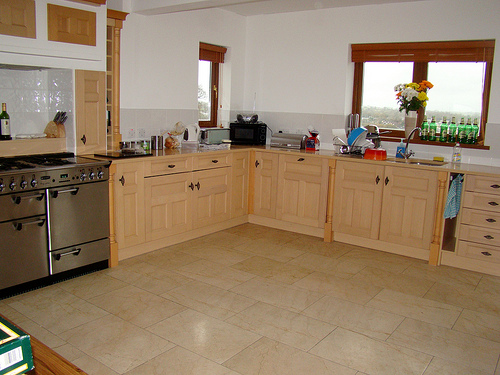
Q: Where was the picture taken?
A: It was taken at the kitchen.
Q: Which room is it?
A: It is a kitchen.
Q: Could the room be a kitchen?
A: Yes, it is a kitchen.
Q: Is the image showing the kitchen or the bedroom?
A: It is showing the kitchen.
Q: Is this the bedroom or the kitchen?
A: It is the kitchen.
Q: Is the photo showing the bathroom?
A: No, the picture is showing the kitchen.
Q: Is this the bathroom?
A: No, it is the kitchen.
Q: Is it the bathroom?
A: No, it is the kitchen.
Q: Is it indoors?
A: Yes, it is indoors.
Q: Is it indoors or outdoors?
A: It is indoors.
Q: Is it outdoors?
A: No, it is indoors.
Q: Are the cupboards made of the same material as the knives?
A: Yes, both the cupboards and the knives are made of wood.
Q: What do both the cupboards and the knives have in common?
A: The material, both the cupboards and the knives are wooden.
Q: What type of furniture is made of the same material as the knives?
A: The cupboards are made of the same material as the knives.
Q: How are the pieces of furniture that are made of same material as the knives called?
A: The pieces of furniture are cupboards.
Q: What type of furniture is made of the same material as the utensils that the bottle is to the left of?
A: The cupboards are made of the same material as the knives.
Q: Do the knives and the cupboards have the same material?
A: Yes, both the knives and the cupboards are made of wood.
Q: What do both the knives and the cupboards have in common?
A: The material, both the knives and the cupboards are wooden.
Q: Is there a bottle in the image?
A: Yes, there is a bottle.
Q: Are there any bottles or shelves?
A: Yes, there is a bottle.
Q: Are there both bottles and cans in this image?
A: No, there is a bottle but no cans.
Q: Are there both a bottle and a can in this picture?
A: No, there is a bottle but no cans.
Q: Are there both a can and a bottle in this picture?
A: No, there is a bottle but no cans.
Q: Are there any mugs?
A: No, there are no mugs.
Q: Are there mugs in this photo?
A: No, there are no mugs.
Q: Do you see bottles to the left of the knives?
A: Yes, there is a bottle to the left of the knives.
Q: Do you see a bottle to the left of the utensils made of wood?
A: Yes, there is a bottle to the left of the knives.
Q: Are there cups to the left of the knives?
A: No, there is a bottle to the left of the knives.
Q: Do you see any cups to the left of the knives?
A: No, there is a bottle to the left of the knives.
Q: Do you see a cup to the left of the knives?
A: No, there is a bottle to the left of the knives.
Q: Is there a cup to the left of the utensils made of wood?
A: No, there is a bottle to the left of the knives.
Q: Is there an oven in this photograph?
A: Yes, there is an oven.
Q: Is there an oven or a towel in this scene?
A: Yes, there is an oven.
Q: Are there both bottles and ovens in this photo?
A: Yes, there are both an oven and a bottle.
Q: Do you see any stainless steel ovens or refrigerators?
A: Yes, there is a stainless steel oven.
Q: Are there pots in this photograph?
A: No, there are no pots.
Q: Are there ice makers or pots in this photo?
A: No, there are no pots or ice makers.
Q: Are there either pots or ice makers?
A: No, there are no pots or ice makers.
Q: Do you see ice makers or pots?
A: No, there are no pots or ice makers.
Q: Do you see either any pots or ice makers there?
A: No, there are no pots or ice makers.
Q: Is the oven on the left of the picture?
A: Yes, the oven is on the left of the image.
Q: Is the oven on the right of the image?
A: No, the oven is on the left of the image.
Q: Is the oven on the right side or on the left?
A: The oven is on the left of the image.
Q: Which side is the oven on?
A: The oven is on the left of the image.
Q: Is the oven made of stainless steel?
A: Yes, the oven is made of stainless steel.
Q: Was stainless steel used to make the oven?
A: Yes, the oven is made of stainless steel.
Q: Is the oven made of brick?
A: No, the oven is made of stainless steel.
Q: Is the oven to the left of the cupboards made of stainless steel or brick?
A: The oven is made of stainless steel.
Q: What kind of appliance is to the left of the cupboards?
A: The appliance is an oven.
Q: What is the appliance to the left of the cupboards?
A: The appliance is an oven.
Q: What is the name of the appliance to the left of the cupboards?
A: The appliance is an oven.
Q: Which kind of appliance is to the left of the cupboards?
A: The appliance is an oven.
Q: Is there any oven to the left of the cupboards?
A: Yes, there is an oven to the left of the cupboards.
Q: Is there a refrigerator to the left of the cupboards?
A: No, there is an oven to the left of the cupboards.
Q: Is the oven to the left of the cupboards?
A: Yes, the oven is to the left of the cupboards.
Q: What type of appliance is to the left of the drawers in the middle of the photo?
A: The appliance is an oven.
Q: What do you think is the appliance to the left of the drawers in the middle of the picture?
A: The appliance is an oven.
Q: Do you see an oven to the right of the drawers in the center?
A: No, the oven is to the left of the drawers.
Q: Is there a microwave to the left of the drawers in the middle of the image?
A: No, there is an oven to the left of the drawers.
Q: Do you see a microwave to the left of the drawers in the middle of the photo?
A: No, there is an oven to the left of the drawers.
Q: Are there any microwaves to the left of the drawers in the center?
A: No, there is an oven to the left of the drawers.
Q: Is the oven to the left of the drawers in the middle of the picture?
A: Yes, the oven is to the left of the drawers.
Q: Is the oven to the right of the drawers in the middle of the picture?
A: No, the oven is to the left of the drawers.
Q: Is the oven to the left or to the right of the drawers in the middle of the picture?
A: The oven is to the left of the drawers.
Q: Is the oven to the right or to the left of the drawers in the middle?
A: The oven is to the left of the drawers.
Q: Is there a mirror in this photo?
A: No, there are no mirrors.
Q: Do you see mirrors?
A: No, there are no mirrors.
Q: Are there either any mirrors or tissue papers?
A: No, there are no mirrors or tissue papers.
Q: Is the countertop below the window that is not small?
A: Yes, the countertop is below the window.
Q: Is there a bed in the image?
A: No, there are no beds.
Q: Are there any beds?
A: No, there are no beds.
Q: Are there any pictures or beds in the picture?
A: No, there are no beds or pictures.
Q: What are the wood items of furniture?
A: The pieces of furniture are cupboards.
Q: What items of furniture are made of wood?
A: The pieces of furniture are cupboards.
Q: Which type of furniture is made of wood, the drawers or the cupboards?
A: The cupboards are made of wood.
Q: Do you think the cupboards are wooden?
A: Yes, the cupboards are wooden.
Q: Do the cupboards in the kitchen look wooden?
A: Yes, the cupboards are wooden.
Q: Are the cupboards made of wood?
A: Yes, the cupboards are made of wood.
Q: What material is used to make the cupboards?
A: The cupboards are made of wood.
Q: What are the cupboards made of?
A: The cupboards are made of wood.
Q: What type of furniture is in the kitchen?
A: The pieces of furniture are cupboards.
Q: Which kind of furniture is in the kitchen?
A: The pieces of furniture are cupboards.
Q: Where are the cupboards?
A: The cupboards are in the kitchen.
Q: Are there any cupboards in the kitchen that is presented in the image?
A: Yes, there are cupboards in the kitchen.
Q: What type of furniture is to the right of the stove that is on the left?
A: The pieces of furniture are cupboards.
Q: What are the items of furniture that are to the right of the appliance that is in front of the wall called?
A: The pieces of furniture are cupboards.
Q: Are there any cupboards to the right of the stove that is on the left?
A: Yes, there are cupboards to the right of the stove.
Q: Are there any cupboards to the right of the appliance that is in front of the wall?
A: Yes, there are cupboards to the right of the stove.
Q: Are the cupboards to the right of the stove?
A: Yes, the cupboards are to the right of the stove.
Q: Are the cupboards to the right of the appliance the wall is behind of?
A: Yes, the cupboards are to the right of the stove.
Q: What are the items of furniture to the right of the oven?
A: The pieces of furniture are cupboards.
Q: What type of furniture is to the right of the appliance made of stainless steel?
A: The pieces of furniture are cupboards.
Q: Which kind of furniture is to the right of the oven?
A: The pieces of furniture are cupboards.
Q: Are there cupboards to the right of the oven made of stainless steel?
A: Yes, there are cupboards to the right of the oven.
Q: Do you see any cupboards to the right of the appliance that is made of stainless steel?
A: Yes, there are cupboards to the right of the oven.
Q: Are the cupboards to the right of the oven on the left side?
A: Yes, the cupboards are to the right of the oven.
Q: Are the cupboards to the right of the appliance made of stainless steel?
A: Yes, the cupboards are to the right of the oven.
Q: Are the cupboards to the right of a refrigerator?
A: No, the cupboards are to the right of the oven.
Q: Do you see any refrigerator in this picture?
A: No, there are no refrigerators.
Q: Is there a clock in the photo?
A: No, there are no clocks.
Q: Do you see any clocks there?
A: No, there are no clocks.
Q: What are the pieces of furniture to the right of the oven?
A: The pieces of furniture are drawers.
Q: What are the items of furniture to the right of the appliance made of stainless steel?
A: The pieces of furniture are drawers.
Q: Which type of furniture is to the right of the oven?
A: The pieces of furniture are drawers.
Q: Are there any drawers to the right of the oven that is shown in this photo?
A: Yes, there are drawers to the right of the oven.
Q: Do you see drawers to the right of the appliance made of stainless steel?
A: Yes, there are drawers to the right of the oven.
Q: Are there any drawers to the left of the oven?
A: No, the drawers are to the right of the oven.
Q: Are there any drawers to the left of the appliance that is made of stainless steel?
A: No, the drawers are to the right of the oven.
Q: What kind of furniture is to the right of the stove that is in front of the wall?
A: The pieces of furniture are drawers.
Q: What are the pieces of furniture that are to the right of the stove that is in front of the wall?
A: The pieces of furniture are drawers.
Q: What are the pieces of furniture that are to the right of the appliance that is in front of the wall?
A: The pieces of furniture are drawers.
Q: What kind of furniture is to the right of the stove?
A: The pieces of furniture are drawers.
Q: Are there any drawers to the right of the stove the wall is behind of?
A: Yes, there are drawers to the right of the stove.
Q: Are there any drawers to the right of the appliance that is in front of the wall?
A: Yes, there are drawers to the right of the stove.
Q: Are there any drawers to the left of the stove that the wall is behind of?
A: No, the drawers are to the right of the stove.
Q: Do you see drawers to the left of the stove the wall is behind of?
A: No, the drawers are to the right of the stove.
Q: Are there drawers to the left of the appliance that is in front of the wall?
A: No, the drawers are to the right of the stove.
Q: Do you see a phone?
A: Yes, there is a phone.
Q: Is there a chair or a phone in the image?
A: Yes, there is a phone.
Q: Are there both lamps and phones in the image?
A: No, there is a phone but no lamps.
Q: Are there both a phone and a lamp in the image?
A: No, there is a phone but no lamps.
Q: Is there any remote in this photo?
A: No, there are no remote controls.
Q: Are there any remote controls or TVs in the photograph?
A: No, there are no remote controls or tvs.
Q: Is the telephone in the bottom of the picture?
A: Yes, the telephone is in the bottom of the image.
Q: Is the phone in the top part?
A: No, the phone is in the bottom of the image.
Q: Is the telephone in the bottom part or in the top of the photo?
A: The telephone is in the bottom of the image.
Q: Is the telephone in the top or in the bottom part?
A: The telephone is in the bottom of the image.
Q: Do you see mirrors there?
A: No, there are no mirrors.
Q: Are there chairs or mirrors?
A: No, there are no mirrors or chairs.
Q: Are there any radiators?
A: No, there are no radiators.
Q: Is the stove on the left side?
A: Yes, the stove is on the left of the image.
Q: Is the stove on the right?
A: No, the stove is on the left of the image.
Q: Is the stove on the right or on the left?
A: The stove is on the left of the image.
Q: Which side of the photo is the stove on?
A: The stove is on the left of the image.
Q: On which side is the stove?
A: The stove is on the left of the image.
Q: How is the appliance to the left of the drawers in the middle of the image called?
A: The appliance is a stove.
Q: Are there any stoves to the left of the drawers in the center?
A: Yes, there is a stove to the left of the drawers.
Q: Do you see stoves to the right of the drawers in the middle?
A: No, the stove is to the left of the drawers.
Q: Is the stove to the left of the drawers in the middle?
A: Yes, the stove is to the left of the drawers.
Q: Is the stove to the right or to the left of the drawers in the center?
A: The stove is to the left of the drawers.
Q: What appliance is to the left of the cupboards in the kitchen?
A: The appliance is a stove.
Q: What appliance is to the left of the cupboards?
A: The appliance is a stove.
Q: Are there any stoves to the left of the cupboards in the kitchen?
A: Yes, there is a stove to the left of the cupboards.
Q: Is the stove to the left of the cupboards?
A: Yes, the stove is to the left of the cupboards.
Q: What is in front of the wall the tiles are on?
A: The stove is in front of the wall.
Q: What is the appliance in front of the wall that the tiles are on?
A: The appliance is a stove.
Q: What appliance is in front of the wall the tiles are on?
A: The appliance is a stove.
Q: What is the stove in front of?
A: The stove is in front of the wall.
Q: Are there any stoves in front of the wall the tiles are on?
A: Yes, there is a stove in front of the wall.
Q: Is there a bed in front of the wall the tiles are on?
A: No, there is a stove in front of the wall.